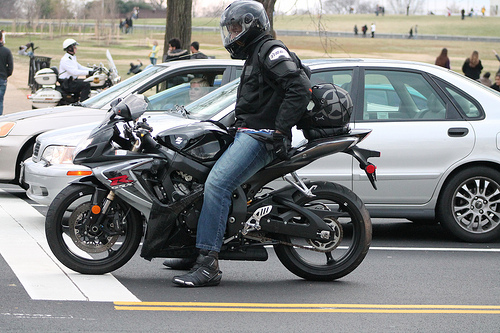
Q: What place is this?
A: It is a street.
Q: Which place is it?
A: It is a street.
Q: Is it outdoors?
A: Yes, it is outdoors.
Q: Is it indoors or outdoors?
A: It is outdoors.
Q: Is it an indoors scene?
A: No, it is outdoors.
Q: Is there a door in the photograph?
A: Yes, there is a door.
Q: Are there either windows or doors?
A: Yes, there is a door.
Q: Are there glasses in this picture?
A: No, there are no glasses.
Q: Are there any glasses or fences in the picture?
A: No, there are no glasses or fences.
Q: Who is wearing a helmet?
A: The man is wearing a helmet.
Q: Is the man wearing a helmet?
A: Yes, the man is wearing a helmet.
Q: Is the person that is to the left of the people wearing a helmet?
A: Yes, the man is wearing a helmet.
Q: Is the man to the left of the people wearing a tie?
A: No, the man is wearing a helmet.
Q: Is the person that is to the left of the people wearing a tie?
A: No, the man is wearing a helmet.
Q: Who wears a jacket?
A: The man wears a jacket.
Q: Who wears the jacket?
A: The man wears a jacket.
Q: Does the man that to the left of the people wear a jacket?
A: Yes, the man wears a jacket.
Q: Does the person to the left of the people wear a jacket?
A: Yes, the man wears a jacket.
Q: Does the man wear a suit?
A: No, the man wears a jacket.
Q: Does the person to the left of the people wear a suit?
A: No, the man wears a jacket.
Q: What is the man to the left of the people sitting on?
A: The man is sitting on the bike.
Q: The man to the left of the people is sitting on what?
A: The man is sitting on the bike.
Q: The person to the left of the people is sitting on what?
A: The man is sitting on the bike.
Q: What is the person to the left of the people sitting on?
A: The man is sitting on the bike.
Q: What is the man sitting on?
A: The man is sitting on the bike.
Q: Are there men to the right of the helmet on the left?
A: Yes, there is a man to the right of the helmet.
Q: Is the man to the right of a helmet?
A: Yes, the man is to the right of a helmet.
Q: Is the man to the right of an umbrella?
A: No, the man is to the right of a helmet.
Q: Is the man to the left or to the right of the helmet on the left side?
A: The man is to the right of the helmet.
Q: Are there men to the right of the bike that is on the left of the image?
A: Yes, there is a man to the right of the bike.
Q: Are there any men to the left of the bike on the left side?
A: No, the man is to the right of the bike.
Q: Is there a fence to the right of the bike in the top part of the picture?
A: No, there is a man to the right of the bike.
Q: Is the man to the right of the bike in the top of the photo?
A: Yes, the man is to the right of the bike.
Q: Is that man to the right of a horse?
A: No, the man is to the right of the bike.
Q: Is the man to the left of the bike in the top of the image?
A: No, the man is to the right of the bike.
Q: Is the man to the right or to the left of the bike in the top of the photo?
A: The man is to the right of the bike.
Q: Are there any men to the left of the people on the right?
A: Yes, there is a man to the left of the people.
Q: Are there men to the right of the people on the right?
A: No, the man is to the left of the people.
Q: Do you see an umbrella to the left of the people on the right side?
A: No, there is a man to the left of the people.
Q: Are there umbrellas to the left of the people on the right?
A: No, there is a man to the left of the people.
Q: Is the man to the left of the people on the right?
A: Yes, the man is to the left of the people.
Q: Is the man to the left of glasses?
A: No, the man is to the left of the people.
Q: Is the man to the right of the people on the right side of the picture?
A: No, the man is to the left of the people.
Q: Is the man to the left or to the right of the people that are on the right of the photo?
A: The man is to the left of the people.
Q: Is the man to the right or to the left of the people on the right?
A: The man is to the left of the people.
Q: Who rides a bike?
A: The man rides a bike.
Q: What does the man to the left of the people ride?
A: The man rides a bike.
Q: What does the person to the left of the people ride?
A: The man rides a bike.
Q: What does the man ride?
A: The man rides a bike.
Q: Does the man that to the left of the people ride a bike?
A: Yes, the man rides a bike.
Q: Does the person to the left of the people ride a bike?
A: Yes, the man rides a bike.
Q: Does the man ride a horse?
A: No, the man rides a bike.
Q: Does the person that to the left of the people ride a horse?
A: No, the man rides a bike.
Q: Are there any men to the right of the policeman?
A: Yes, there is a man to the right of the policeman.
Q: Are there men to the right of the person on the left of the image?
A: Yes, there is a man to the right of the policeman.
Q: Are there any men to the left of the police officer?
A: No, the man is to the right of the police officer.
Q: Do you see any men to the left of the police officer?
A: No, the man is to the right of the police officer.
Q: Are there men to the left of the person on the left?
A: No, the man is to the right of the police officer.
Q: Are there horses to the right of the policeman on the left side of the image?
A: No, there is a man to the right of the police officer.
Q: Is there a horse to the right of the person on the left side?
A: No, there is a man to the right of the police officer.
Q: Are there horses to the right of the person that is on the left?
A: No, there is a man to the right of the police officer.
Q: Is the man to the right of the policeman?
A: Yes, the man is to the right of the policeman.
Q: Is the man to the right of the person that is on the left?
A: Yes, the man is to the right of the policeman.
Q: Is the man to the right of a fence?
A: No, the man is to the right of the policeman.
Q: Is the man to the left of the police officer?
A: No, the man is to the right of the police officer.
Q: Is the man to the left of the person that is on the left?
A: No, the man is to the right of the police officer.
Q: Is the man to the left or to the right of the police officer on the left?
A: The man is to the right of the policeman.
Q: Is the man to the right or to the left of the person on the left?
A: The man is to the right of the policeman.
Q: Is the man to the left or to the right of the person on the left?
A: The man is to the right of the policeman.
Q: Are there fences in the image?
A: No, there are no fences.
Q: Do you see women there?
A: Yes, there is a woman.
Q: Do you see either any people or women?
A: Yes, there is a woman.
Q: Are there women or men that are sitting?
A: Yes, the woman is sitting.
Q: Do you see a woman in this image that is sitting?
A: Yes, there is a woman that is sitting.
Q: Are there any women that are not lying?
A: Yes, there is a woman that is sitting.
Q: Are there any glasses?
A: No, there are no glasses.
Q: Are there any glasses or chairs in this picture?
A: No, there are no glasses or chairs.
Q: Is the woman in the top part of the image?
A: Yes, the woman is in the top of the image.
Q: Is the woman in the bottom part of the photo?
A: No, the woman is in the top of the image.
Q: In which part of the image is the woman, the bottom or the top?
A: The woman is in the top of the image.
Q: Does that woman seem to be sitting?
A: Yes, the woman is sitting.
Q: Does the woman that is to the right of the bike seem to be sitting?
A: Yes, the woman is sitting.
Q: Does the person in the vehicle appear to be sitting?
A: Yes, the woman is sitting.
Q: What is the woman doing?
A: The woman is sitting.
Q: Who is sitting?
A: The woman is sitting.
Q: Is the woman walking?
A: No, the woman is sitting.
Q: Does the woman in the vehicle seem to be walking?
A: No, the woman is sitting.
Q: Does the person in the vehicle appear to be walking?
A: No, the woman is sitting.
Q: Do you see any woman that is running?
A: No, there is a woman but she is sitting.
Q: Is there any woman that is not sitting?
A: No, there is a woman but she is sitting.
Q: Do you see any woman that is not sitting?
A: No, there is a woman but she is sitting.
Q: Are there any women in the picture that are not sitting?
A: No, there is a woman but she is sitting.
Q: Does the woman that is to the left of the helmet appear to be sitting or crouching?
A: The woman is sitting.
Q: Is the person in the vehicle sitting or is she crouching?
A: The woman is sitting.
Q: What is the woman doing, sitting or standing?
A: The woman is sitting.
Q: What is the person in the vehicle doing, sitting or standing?
A: The woman is sitting.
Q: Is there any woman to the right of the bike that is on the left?
A: Yes, there is a woman to the right of the bike.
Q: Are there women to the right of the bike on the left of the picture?
A: Yes, there is a woman to the right of the bike.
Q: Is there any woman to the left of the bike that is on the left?
A: No, the woman is to the right of the bike.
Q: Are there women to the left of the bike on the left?
A: No, the woman is to the right of the bike.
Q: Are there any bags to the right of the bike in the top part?
A: No, there is a woman to the right of the bike.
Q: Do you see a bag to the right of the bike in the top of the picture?
A: No, there is a woman to the right of the bike.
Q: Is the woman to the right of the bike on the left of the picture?
A: Yes, the woman is to the right of the bike.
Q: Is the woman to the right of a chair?
A: No, the woman is to the right of the bike.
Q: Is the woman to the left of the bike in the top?
A: No, the woman is to the right of the bike.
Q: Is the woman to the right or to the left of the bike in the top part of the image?
A: The woman is to the right of the bike.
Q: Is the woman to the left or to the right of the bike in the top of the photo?
A: The woman is to the right of the bike.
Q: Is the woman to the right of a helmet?
A: No, the woman is to the left of a helmet.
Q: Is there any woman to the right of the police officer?
A: Yes, there is a woman to the right of the police officer.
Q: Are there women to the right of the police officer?
A: Yes, there is a woman to the right of the police officer.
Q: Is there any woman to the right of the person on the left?
A: Yes, there is a woman to the right of the police officer.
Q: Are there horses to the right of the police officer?
A: No, there is a woman to the right of the police officer.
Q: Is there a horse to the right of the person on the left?
A: No, there is a woman to the right of the police officer.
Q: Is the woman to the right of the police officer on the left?
A: Yes, the woman is to the right of the policeman.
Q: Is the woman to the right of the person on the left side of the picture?
A: Yes, the woman is to the right of the policeman.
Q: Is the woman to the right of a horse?
A: No, the woman is to the right of the policeman.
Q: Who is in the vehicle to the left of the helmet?
A: The woman is in the vehicle.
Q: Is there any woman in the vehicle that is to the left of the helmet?
A: Yes, there is a woman in the vehicle.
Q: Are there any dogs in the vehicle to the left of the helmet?
A: No, there is a woman in the vehicle.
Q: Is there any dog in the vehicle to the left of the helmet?
A: No, there is a woman in the vehicle.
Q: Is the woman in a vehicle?
A: Yes, the woman is in a vehicle.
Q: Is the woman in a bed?
A: No, the woman is in a vehicle.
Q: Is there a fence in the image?
A: No, there are no fences.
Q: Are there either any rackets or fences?
A: No, there are no fences or rackets.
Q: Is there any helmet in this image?
A: Yes, there is a helmet.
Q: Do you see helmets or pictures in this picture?
A: Yes, there is a helmet.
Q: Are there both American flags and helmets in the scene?
A: No, there is a helmet but no American flags.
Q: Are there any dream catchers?
A: No, there are no dream catchers.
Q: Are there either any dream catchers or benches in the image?
A: No, there are no dream catchers or benches.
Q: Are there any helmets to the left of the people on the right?
A: Yes, there is a helmet to the left of the people.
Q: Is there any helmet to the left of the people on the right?
A: Yes, there is a helmet to the left of the people.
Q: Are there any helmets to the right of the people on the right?
A: No, the helmet is to the left of the people.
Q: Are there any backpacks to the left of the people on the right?
A: No, there is a helmet to the left of the people.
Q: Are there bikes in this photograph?
A: Yes, there is a bike.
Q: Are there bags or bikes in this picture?
A: Yes, there is a bike.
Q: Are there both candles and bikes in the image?
A: No, there is a bike but no candles.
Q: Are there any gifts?
A: No, there are no gifts.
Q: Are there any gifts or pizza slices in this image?
A: No, there are no gifts or pizza slices.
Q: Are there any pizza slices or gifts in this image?
A: No, there are no gifts or pizza slices.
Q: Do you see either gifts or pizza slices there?
A: No, there are no gifts or pizza slices.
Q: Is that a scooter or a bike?
A: That is a bike.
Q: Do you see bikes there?
A: Yes, there is a bike.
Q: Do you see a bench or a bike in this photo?
A: Yes, there is a bike.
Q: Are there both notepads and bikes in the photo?
A: No, there is a bike but no notepads.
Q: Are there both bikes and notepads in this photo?
A: No, there is a bike but no notepads.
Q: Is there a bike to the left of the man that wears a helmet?
A: Yes, there is a bike to the left of the man.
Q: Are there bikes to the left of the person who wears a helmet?
A: Yes, there is a bike to the left of the man.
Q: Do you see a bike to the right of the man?
A: No, the bike is to the left of the man.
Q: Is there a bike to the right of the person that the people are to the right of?
A: No, the bike is to the left of the man.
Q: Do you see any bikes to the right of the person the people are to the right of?
A: No, the bike is to the left of the man.